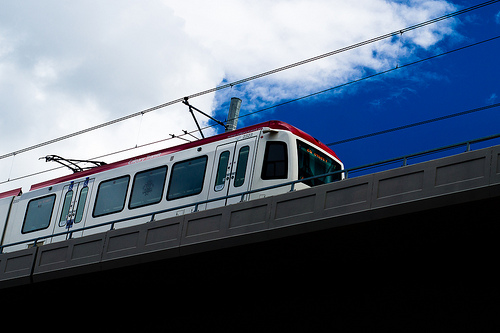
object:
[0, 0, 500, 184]
cable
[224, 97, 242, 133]
pole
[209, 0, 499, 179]
blue sky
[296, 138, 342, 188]
glass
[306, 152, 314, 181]
wiper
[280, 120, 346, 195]
front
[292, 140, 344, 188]
window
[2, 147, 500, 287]
stone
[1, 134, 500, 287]
platform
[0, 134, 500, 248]
metal railing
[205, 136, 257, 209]
doors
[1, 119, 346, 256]
bus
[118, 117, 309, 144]
red roof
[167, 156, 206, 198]
window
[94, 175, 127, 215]
window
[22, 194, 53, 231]
window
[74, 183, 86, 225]
window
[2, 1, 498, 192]
sky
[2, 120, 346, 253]
train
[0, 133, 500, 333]
flyover railroad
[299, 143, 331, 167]
display board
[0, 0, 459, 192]
cloud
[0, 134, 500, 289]
bridge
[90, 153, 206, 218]
panes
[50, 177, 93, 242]
door